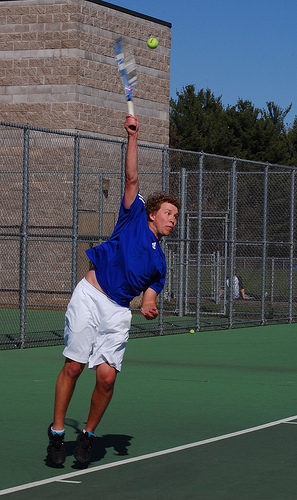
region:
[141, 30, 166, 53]
a green ball in the air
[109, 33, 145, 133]
a blue and white racket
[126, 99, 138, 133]
handle of racket is white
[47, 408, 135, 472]
shadow of a person on ground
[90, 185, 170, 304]
a blue shirt with white stripes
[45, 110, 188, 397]
woman wears a white short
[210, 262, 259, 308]
man sits behind a fence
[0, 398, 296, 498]
a white line on tennis court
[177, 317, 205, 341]
a tennis ball on the ground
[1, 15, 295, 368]
a building behind a tennis court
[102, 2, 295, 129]
blue of daytime sky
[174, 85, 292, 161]
tops of green trees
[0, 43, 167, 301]
corner of gray and tan building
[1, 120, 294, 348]
metal poles on chain link fence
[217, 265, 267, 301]
back of sitting person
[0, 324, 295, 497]
green court with white line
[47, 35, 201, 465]
player jumping up to hit ball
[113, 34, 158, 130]
tennis racket and ball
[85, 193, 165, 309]
blue short sleeved shirt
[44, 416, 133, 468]
shadow of man on court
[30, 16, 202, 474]
woman jumps to hit a ball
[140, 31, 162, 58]
a green ball is in the air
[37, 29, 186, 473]
woman hold a racket with right hand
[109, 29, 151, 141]
a blue, gray and white racket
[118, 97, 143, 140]
handle of racket is white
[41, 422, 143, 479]
shadow cast on the ground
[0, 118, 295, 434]
tennis court is fenced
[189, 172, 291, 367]
a man behind a tennis court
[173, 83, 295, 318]
green trees behind a tennis court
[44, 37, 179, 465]
a man playing tennis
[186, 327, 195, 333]
a yellow ball on the ground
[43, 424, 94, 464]
man wearing black shoes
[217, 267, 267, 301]
a person sitting on the ground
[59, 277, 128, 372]
man wearing white shorts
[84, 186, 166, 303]
man wearing a blue shirt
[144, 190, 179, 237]
man with brown curly hair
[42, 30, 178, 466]
a man about to hit a ball with a tennis racket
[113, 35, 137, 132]
man holding a tennis racket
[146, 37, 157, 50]
a yellow ball flying in the air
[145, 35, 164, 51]
yellow tennis ball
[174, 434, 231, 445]
white lines on the tennis court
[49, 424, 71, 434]
blue and white tennis socks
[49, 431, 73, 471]
hight top black sneakers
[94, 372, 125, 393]
player's knee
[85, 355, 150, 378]
edge of white tennis shorts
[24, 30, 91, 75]
tall stone wall in the background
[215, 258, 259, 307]
man sitting on the ground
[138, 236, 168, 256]
white logo on blue shirt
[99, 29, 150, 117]
blue and white tennis racket